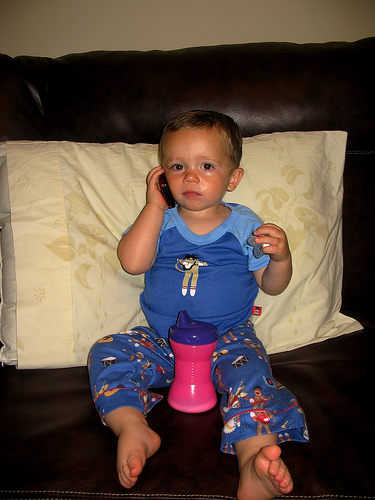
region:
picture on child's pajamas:
[100, 353, 119, 365]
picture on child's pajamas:
[90, 378, 107, 402]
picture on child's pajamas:
[118, 343, 145, 363]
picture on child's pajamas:
[125, 332, 153, 351]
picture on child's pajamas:
[246, 383, 273, 408]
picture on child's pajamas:
[219, 381, 247, 416]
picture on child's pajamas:
[211, 361, 226, 393]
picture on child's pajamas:
[212, 348, 228, 361]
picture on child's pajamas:
[230, 353, 249, 367]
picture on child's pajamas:
[263, 374, 279, 390]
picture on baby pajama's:
[241, 384, 274, 411]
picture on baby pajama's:
[249, 409, 273, 432]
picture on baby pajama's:
[224, 384, 246, 410]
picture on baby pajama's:
[262, 370, 281, 394]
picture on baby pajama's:
[230, 352, 248, 367]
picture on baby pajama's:
[241, 337, 267, 363]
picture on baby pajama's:
[98, 353, 119, 365]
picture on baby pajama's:
[127, 331, 158, 352]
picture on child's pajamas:
[90, 382, 111, 405]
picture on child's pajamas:
[132, 385, 151, 408]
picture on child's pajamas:
[96, 333, 117, 346]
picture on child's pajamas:
[129, 331, 153, 355]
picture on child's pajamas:
[220, 329, 239, 346]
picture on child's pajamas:
[241, 334, 266, 362]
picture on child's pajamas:
[218, 379, 243, 418]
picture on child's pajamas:
[241, 384, 275, 411]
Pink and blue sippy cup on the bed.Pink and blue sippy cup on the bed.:
[248, 370, 320, 440]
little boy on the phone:
[69, 100, 341, 498]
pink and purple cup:
[163, 308, 228, 423]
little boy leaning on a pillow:
[0, 103, 374, 497]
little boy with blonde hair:
[78, 98, 316, 498]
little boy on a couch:
[6, 27, 352, 496]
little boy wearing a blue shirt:
[81, 96, 330, 497]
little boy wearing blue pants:
[78, 106, 327, 498]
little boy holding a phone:
[72, 88, 319, 497]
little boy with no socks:
[59, 86, 320, 496]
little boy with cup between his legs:
[72, 82, 310, 497]